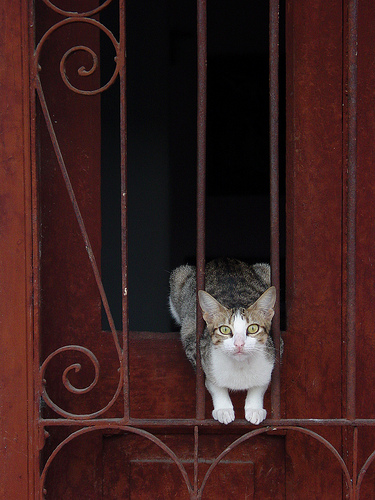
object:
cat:
[168, 258, 276, 426]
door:
[0, 1, 375, 500]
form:
[31, 17, 119, 96]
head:
[198, 285, 278, 363]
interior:
[101, 0, 288, 335]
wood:
[37, 0, 374, 500]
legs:
[244, 385, 267, 412]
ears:
[198, 289, 231, 325]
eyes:
[218, 325, 232, 338]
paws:
[212, 408, 235, 425]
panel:
[131, 459, 256, 500]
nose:
[233, 339, 245, 348]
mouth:
[233, 351, 248, 358]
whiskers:
[204, 342, 278, 361]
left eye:
[246, 323, 260, 336]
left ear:
[246, 286, 277, 322]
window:
[96, 4, 283, 335]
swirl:
[39, 345, 123, 420]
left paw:
[244, 407, 267, 425]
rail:
[40, 418, 375, 427]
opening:
[205, 0, 272, 262]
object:
[40, 424, 195, 500]